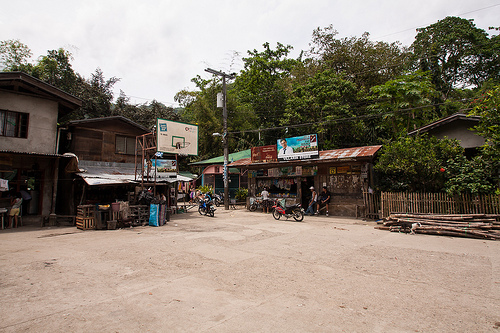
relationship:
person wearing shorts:
[1, 187, 28, 232] [9, 204, 21, 218]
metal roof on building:
[335, 140, 360, 156] [245, 129, 368, 204]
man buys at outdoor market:
[258, 187, 272, 209] [247, 166, 316, 212]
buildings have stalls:
[0, 60, 498, 242] [2, 76, 497, 247]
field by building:
[2, 221, 497, 331] [1, 71, 83, 232]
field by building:
[2, 221, 497, 331] [63, 112, 175, 232]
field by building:
[2, 221, 497, 331] [397, 110, 499, 212]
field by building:
[2, 221, 497, 331] [225, 150, 380, 222]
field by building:
[2, 221, 497, 331] [192, 148, 250, 204]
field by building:
[2, 221, 497, 331] [177, 167, 197, 200]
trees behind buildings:
[1, 14, 498, 148] [1, 69, 492, 228]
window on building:
[0, 109, 28, 138] [1, 71, 83, 232]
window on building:
[113, 134, 143, 155] [58, 113, 158, 223]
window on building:
[240, 169, 249, 190] [229, 143, 381, 221]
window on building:
[0, 109, 28, 138] [185, 149, 251, 198]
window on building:
[0, 109, 28, 138] [402, 109, 499, 164]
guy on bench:
[314, 186, 330, 216] [304, 203, 353, 216]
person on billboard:
[278, 137, 293, 154] [277, 134, 319, 159]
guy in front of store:
[313, 184, 331, 219] [223, 141, 384, 220]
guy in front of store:
[305, 183, 319, 218] [223, 141, 384, 220]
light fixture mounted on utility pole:
[214, 87, 225, 109] [218, 117, 231, 173]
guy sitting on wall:
[314, 186, 330, 216] [333, 173, 357, 198]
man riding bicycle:
[188, 190, 220, 216] [198, 201, 216, 214]